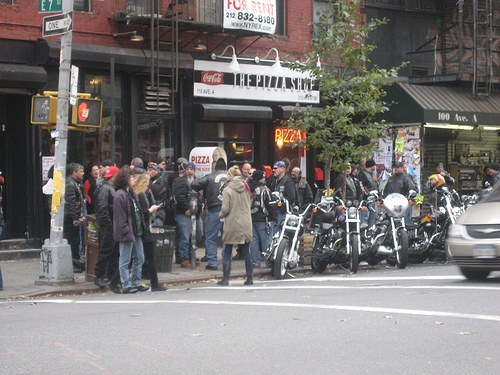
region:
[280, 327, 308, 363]
part of a road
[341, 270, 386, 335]
part of a line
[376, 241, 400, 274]
part of a qheel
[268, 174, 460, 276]
motorcycles parked on street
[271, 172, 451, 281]
group of motorcycles near street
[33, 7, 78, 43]
one way sign on post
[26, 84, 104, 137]
pedestrian crossing signal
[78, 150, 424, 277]
people in a group on street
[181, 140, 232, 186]
pizza sign behind people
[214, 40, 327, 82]
white lights hanging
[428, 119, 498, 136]
light under building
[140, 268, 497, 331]
crosswalk on street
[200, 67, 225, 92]
coca cola logo on sign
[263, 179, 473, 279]
several motorcycles parked at the curb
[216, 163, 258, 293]
a woman in a hooded jacket walks in the crosswalk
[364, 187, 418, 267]
this motorcycle has a little windshield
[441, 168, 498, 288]
a silver car about to enter the intersection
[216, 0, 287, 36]
a sign advertises a place for rent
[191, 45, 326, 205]
a pizza shop is located behind the crowd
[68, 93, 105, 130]
the sign cautions pedestrians not to cross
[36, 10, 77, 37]
the sign indicates this is a one way street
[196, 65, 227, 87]
the pizza shop serves Coca-Cola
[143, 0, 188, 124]
a fire escape ladder above the crowd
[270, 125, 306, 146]
Neon pizza sign in window.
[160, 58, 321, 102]
Sign above window reading, The Pizza Shop.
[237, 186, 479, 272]
A row of motorcycles parked on the street.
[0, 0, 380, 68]
Red brick on the building above the stores.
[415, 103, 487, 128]
Address of 100 Ave. A on awning.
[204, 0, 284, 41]
For rent sign of space above store.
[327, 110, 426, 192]
A board with informational papers attached.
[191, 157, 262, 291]
A woman with a light brown coat.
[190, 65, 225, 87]
Coca-cola logo on left side of Pizza Shop sign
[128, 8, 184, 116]
Fire escape ladder attached to balcony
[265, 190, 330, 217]
a motorcycles handle bar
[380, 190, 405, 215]
a motorcycle fairing to reduce air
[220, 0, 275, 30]
a for rent banner on the building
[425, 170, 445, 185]
a full motorcycle racing helmet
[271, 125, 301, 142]
a neon light pizza sign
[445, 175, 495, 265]
a beige minivan at the intersection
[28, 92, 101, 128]
a pedestrian crossing signal light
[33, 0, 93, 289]
a street sign and traffic light pole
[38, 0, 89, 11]
a green street sign on the pole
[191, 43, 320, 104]
a business banner sign with lighting